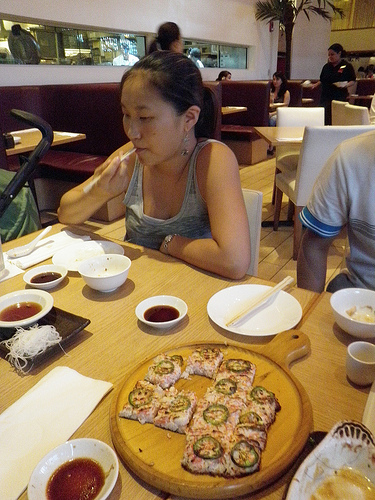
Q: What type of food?
A: Pizza.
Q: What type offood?
A: Pizza.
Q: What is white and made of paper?
A: Napkin.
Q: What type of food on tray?
A: Pizza.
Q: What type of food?
A: Pizza.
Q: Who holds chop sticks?
A: The woman.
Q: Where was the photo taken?
A: In a restaurant.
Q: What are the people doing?
A: Eating.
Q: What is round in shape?
A: The plate.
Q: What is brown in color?
A: The table.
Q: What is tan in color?
A: Table.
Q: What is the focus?
A: People eating at a restaurant.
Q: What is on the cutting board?
A: Pizza.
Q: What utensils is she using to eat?
A: Chop sticks.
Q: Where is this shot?
A: Table.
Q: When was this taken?
A: Daytime.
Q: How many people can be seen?
A: 6.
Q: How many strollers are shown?
A: 1.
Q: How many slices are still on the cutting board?
A: 11.